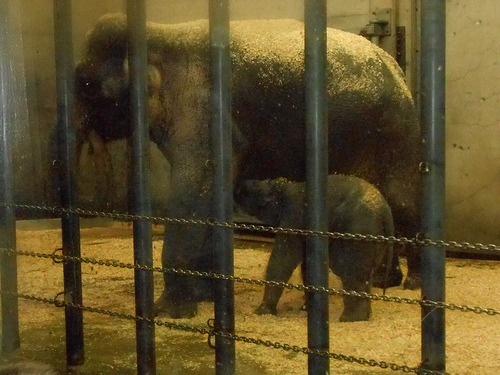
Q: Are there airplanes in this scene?
A: No, there are no airplanes.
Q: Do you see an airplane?
A: No, there are no airplanes.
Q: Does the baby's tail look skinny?
A: Yes, the tail is skinny.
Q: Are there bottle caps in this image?
A: No, there are no bottle caps.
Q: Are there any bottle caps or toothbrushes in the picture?
A: No, there are no bottle caps or toothbrushes.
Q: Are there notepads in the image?
A: No, there are no notepads.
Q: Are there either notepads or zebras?
A: No, there are no notepads or zebras.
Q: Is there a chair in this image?
A: No, there are no chairs.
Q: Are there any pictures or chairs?
A: No, there are no chairs or pictures.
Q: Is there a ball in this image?
A: No, there are no balls.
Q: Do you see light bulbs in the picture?
A: No, there are no light bulbs.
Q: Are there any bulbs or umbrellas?
A: No, there are no bulbs or umbrellas.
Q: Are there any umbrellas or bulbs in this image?
A: No, there are no bulbs or umbrellas.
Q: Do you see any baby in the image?
A: Yes, there is a baby.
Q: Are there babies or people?
A: Yes, there is a baby.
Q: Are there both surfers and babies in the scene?
A: No, there is a baby but no surfers.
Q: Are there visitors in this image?
A: No, there are no visitors.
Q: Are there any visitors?
A: No, there are no visitors.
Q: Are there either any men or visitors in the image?
A: No, there are no visitors or men.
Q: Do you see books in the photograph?
A: No, there are no books.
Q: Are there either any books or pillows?
A: No, there are no books or pillows.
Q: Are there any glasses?
A: No, there are no glasses.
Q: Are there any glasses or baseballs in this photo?
A: No, there are no glasses or baseballs.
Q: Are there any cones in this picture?
A: No, there are no cones.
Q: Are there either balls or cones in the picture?
A: No, there are no cones or balls.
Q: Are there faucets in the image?
A: No, there are no faucets.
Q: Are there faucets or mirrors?
A: No, there are no faucets or mirrors.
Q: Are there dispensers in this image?
A: No, there are no dispensers.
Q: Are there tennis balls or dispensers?
A: No, there are no dispensers or tennis balls.